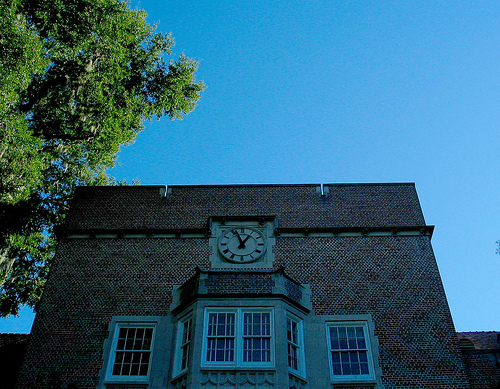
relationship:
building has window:
[1, 182, 498, 388] [109, 312, 153, 382]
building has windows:
[1, 182, 498, 388] [178, 309, 197, 376]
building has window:
[1, 182, 498, 388] [199, 304, 274, 369]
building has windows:
[1, 182, 498, 388] [284, 311, 308, 378]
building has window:
[1, 182, 498, 388] [322, 319, 380, 378]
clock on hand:
[210, 215, 275, 268] [244, 223, 254, 253]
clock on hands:
[210, 215, 275, 268] [234, 228, 247, 250]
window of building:
[113, 318, 154, 378] [1, 182, 500, 389]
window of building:
[199, 304, 274, 369] [1, 182, 500, 389]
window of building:
[323, 317, 373, 383] [1, 182, 500, 389]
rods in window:
[209, 312, 234, 359] [205, 310, 236, 369]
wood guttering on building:
[45, 216, 437, 246] [16, 176, 472, 388]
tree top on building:
[2, 0, 204, 315] [1, 182, 498, 388]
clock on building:
[210, 215, 275, 268] [1, 182, 498, 388]